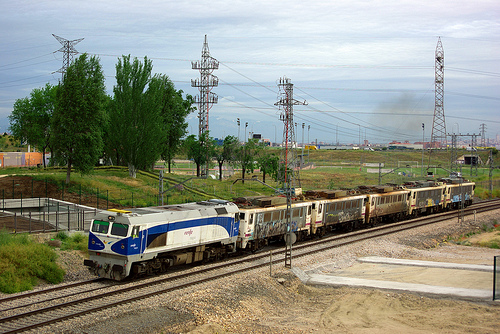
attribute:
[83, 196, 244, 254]
train front — blue, white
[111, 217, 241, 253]
swirl — blue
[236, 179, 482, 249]
train cars — silver, full, multiple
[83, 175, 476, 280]
train — short, blue, grey, commuter , white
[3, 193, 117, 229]
tunnel — grey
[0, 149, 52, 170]
building — orange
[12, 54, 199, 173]
trees — green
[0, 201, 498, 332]
gravel — brown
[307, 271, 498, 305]
slabs — concrete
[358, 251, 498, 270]
slabs — concrete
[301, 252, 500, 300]
slabs — grey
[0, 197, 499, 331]
tracks — close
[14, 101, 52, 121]
leaves — green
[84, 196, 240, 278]
engine — blue, white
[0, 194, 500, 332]
train tracks — multiple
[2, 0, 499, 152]
sky — blue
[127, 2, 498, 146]
clouds — white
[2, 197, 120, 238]
opening — concrete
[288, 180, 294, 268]
pole — metal